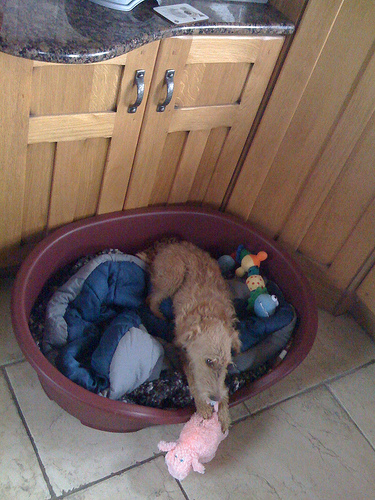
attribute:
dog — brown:
[131, 232, 240, 433]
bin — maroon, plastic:
[8, 201, 321, 435]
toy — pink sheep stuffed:
[154, 411, 229, 477]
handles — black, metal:
[125, 65, 176, 116]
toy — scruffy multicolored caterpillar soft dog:
[213, 236, 291, 332]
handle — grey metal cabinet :
[127, 68, 146, 114]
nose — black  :
[208, 394, 218, 400]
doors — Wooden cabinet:
[1, 30, 284, 204]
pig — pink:
[145, 394, 230, 481]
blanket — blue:
[39, 246, 169, 400]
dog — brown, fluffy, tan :
[146, 234, 236, 428]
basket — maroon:
[8, 197, 320, 446]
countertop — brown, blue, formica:
[0, 1, 297, 59]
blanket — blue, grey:
[50, 255, 312, 344]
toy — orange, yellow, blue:
[234, 246, 281, 318]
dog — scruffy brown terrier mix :
[148, 233, 256, 433]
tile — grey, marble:
[326, 360, 373, 458]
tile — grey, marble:
[243, 308, 373, 413]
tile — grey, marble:
[180, 386, 373, 498]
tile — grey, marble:
[59, 447, 188, 498]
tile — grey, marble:
[4, 355, 193, 498]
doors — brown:
[26, 1, 280, 244]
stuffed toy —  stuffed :
[148, 407, 232, 481]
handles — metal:
[122, 67, 177, 113]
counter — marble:
[0, 0, 297, 64]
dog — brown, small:
[140, 227, 247, 435]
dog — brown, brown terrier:
[145, 235, 243, 436]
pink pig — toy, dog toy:
[153, 398, 229, 477]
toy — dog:
[231, 242, 280, 318]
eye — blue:
[178, 457, 184, 462]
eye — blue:
[173, 452, 178, 458]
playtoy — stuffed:
[219, 244, 278, 320]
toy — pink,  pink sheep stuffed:
[155, 399, 227, 479]